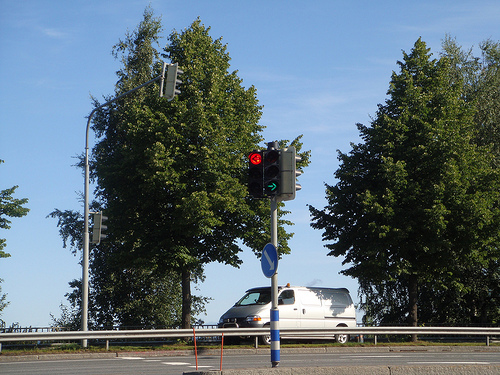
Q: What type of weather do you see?
A: It is clear.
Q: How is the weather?
A: It is clear.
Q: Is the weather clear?
A: Yes, it is clear.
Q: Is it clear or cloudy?
A: It is clear.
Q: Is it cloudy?
A: No, it is clear.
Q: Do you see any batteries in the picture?
A: No, there are no batteries.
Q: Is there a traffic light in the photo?
A: Yes, there is a traffic light.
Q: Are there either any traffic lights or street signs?
A: Yes, there is a traffic light.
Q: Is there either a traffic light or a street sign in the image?
A: Yes, there is a traffic light.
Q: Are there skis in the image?
A: No, there are no skis.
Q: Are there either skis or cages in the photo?
A: No, there are no skis or cages.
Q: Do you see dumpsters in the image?
A: No, there are no dumpsters.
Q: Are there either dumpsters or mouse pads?
A: No, there are no dumpsters or mouse pads.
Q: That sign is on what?
A: The sign is on the pole.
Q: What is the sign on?
A: The sign is on the pole.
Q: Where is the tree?
A: The tree is on the road.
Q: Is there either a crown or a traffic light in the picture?
A: Yes, there is a traffic light.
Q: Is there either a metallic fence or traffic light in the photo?
A: Yes, there is a metal traffic light.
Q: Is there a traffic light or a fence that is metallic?
A: Yes, the traffic light is metallic.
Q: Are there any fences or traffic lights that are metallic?
A: Yes, the traffic light is metallic.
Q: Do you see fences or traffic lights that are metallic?
A: Yes, the traffic light is metallic.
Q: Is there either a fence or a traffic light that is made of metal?
A: Yes, the traffic light is made of metal.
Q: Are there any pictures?
A: No, there are no pictures.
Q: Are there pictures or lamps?
A: No, there are no pictures or lamps.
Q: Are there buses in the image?
A: No, there are no buses.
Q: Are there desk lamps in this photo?
A: No, there are no desk lamps.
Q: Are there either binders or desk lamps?
A: No, there are no desk lamps or binders.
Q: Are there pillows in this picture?
A: No, there are no pillows.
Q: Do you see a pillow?
A: No, there are no pillows.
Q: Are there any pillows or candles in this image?
A: No, there are no pillows or candles.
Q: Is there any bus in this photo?
A: No, there are no buses.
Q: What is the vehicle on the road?
A: The vehicle is a van.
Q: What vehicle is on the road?
A: The vehicle is a van.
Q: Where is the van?
A: The van is on the road.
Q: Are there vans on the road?
A: Yes, there is a van on the road.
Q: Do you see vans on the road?
A: Yes, there is a van on the road.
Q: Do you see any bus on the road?
A: No, there is a van on the road.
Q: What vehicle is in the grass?
A: The vehicle is a van.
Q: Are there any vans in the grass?
A: Yes, there is a van in the grass.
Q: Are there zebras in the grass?
A: No, there is a van in the grass.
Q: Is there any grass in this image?
A: Yes, there is grass.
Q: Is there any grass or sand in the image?
A: Yes, there is grass.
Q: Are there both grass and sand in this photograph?
A: No, there is grass but no sand.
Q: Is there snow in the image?
A: No, there is no snow.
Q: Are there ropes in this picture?
A: No, there are no ropes.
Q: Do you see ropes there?
A: No, there are no ropes.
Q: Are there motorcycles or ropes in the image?
A: No, there are no ropes or motorcycles.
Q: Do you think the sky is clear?
A: Yes, the sky is clear.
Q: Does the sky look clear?
A: Yes, the sky is clear.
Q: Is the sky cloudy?
A: No, the sky is clear.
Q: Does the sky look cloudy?
A: No, the sky is clear.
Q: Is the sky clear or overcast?
A: The sky is clear.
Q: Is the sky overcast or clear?
A: The sky is clear.